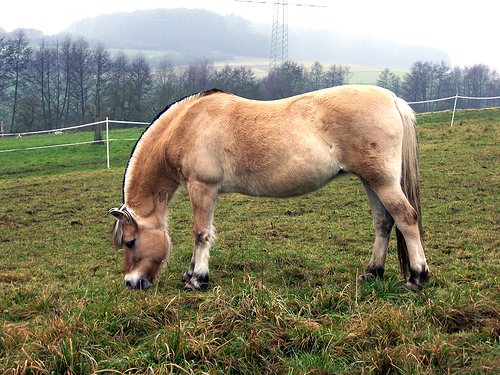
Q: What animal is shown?
A: A horse.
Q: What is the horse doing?
A: Eating grass.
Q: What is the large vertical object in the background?
A: A metal tower.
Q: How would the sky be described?
A: Cloudy / overcast.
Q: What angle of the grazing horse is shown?
A: The side.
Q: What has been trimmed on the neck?
A: The mane.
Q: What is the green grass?
A: Pasture.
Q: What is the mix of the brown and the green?
A: Grass.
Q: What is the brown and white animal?
A: A pony.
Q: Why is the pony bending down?
A: To eat grass.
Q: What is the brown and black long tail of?
A: A pony.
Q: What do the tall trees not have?
A: Leaves.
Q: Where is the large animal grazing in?
A: A pasture.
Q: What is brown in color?
A: The horse.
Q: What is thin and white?
A: The fence.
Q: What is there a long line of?
A: Trees.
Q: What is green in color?
A: The grass.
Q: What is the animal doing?
A: Standing.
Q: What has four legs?
A: The animal.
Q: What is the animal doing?
A: Eating.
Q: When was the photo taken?
A: During the daytime.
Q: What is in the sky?
A: Clouds.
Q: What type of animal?
A: Horse.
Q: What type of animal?
A: Horse.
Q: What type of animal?
A: Horse.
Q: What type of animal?
A: Horse.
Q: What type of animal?
A: Horse.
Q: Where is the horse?
A: In a field.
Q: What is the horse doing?
A: Grazing.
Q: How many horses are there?
A: One.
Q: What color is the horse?
A: Tan.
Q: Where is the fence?
A: Behind the horse.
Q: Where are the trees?
A: Behind the field.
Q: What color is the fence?
A: White.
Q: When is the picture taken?
A: In the daytime.